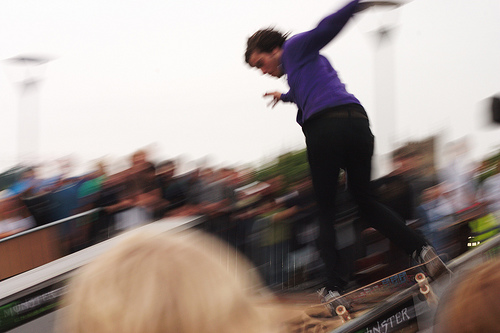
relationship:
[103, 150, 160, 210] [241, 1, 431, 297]
person watching skateboarder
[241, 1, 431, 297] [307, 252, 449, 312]
skateboarder on skateboard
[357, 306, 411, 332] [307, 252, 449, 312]
logo under skateboard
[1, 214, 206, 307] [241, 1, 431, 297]
handrail in front of skateboarder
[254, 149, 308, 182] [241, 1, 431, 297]
trees behind skateboarder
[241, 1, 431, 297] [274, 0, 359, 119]
skateboarder in shirt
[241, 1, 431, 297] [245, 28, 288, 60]
skateboarder has hair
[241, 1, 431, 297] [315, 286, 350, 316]
skateboarder with sneaker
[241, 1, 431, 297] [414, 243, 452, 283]
skateboarder with sneaker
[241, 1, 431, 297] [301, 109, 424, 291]
skateboarder wearing jeans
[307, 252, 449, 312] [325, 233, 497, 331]
skateboard going down ramp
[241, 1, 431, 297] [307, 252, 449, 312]
skateboarder riding skateboard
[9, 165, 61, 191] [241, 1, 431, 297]
person watching skateboarder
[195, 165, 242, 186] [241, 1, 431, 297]
person watching skateboarder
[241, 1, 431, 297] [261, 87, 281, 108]
skateboarder has hand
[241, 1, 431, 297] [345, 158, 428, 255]
skateboarder has leg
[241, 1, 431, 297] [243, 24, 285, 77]
skateboarder has head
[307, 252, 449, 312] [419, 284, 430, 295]
skateboard has wheel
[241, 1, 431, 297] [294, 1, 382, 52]
skateboarder has arm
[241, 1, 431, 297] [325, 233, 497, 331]
skateboarder on rail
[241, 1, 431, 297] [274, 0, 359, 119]
skateboarder with shirt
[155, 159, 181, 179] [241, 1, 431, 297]
person watching skateboarder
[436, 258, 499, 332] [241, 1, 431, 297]
head on skateboarder